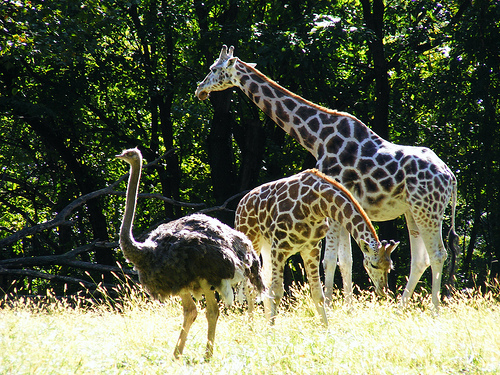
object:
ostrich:
[113, 146, 267, 366]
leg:
[197, 274, 221, 365]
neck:
[118, 161, 144, 266]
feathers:
[153, 236, 208, 259]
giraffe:
[193, 42, 460, 313]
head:
[193, 43, 258, 101]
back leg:
[397, 206, 433, 312]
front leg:
[313, 160, 342, 302]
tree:
[1, 0, 126, 307]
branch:
[0, 175, 63, 214]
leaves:
[52, 59, 68, 73]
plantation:
[0, 0, 500, 375]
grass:
[0, 284, 500, 375]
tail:
[446, 168, 462, 297]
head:
[110, 146, 145, 171]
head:
[354, 237, 400, 300]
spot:
[325, 134, 345, 155]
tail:
[241, 233, 268, 293]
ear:
[227, 57, 238, 68]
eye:
[211, 66, 218, 74]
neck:
[228, 57, 339, 159]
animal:
[234, 166, 401, 329]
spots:
[335, 117, 352, 138]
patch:
[138, 314, 180, 348]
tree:
[282, 0, 500, 298]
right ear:
[245, 62, 258, 68]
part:
[0, 281, 90, 375]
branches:
[106, 188, 208, 208]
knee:
[205, 306, 222, 323]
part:
[200, 278, 219, 312]